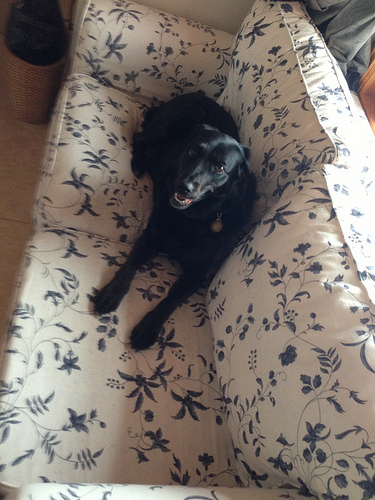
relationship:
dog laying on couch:
[84, 85, 255, 354] [3, 2, 372, 498]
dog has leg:
[84, 85, 255, 354] [89, 233, 165, 320]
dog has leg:
[84, 85, 255, 354] [125, 273, 206, 351]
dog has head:
[84, 85, 255, 354] [168, 121, 253, 219]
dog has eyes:
[84, 85, 255, 354] [210, 160, 225, 176]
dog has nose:
[84, 85, 255, 354] [178, 181, 195, 193]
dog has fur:
[84, 85, 255, 354] [102, 95, 259, 341]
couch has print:
[3, 2, 372, 498] [241, 61, 287, 130]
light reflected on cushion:
[342, 99, 371, 189] [231, 6, 364, 174]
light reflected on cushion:
[342, 99, 371, 189] [236, 184, 368, 492]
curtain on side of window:
[307, 2, 374, 79] [356, 78, 371, 119]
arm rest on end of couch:
[76, 14, 223, 85] [20, 15, 368, 427]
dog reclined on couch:
[84, 85, 255, 354] [3, 2, 372, 498]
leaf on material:
[312, 373, 322, 388] [202, 162, 373, 498]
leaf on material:
[297, 373, 312, 385] [202, 162, 373, 498]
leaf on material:
[300, 385, 313, 394] [202, 162, 373, 498]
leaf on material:
[325, 394, 345, 412] [202, 162, 373, 498]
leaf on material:
[346, 387, 367, 405] [202, 162, 373, 498]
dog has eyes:
[84, 85, 255, 354] [189, 141, 234, 174]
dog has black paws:
[84, 85, 255, 354] [128, 308, 168, 347]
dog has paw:
[84, 85, 255, 354] [90, 288, 121, 314]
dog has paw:
[84, 85, 255, 354] [130, 155, 147, 177]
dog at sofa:
[84, 85, 255, 354] [1, 2, 373, 498]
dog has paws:
[84, 85, 255, 354] [130, 310, 165, 348]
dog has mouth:
[84, 85, 255, 354] [167, 180, 209, 228]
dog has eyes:
[84, 85, 255, 354] [179, 139, 225, 176]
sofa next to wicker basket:
[45, 9, 311, 135] [5, 38, 67, 124]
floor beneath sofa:
[1, 105, 49, 348] [1, 2, 373, 498]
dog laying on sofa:
[84, 85, 255, 354] [1, 2, 373, 498]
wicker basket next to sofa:
[5, 38, 67, 124] [1, 2, 373, 498]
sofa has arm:
[0, 0, 374, 498] [118, 12, 281, 92]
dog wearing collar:
[84, 85, 255, 354] [208, 207, 222, 233]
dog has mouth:
[84, 85, 255, 354] [170, 184, 200, 205]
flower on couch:
[99, 27, 133, 70] [3, 2, 372, 498]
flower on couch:
[137, 425, 169, 454] [3, 2, 372, 498]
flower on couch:
[101, 30, 128, 66] [3, 2, 372, 498]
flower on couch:
[245, 15, 276, 48] [3, 2, 372, 498]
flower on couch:
[262, 200, 300, 235] [3, 2, 372, 498]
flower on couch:
[61, 167, 93, 192] [3, 2, 372, 498]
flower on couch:
[288, 238, 310, 256] [3, 2, 372, 498]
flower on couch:
[170, 388, 209, 420] [3, 2, 372, 498]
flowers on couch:
[296, 369, 326, 396] [3, 2, 372, 498]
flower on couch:
[58, 354, 81, 374] [3, 2, 372, 498]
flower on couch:
[313, 88, 331, 106] [3, 2, 372, 498]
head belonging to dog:
[167, 124, 244, 214] [84, 85, 255, 354]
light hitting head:
[180, 131, 248, 200] [167, 124, 244, 214]